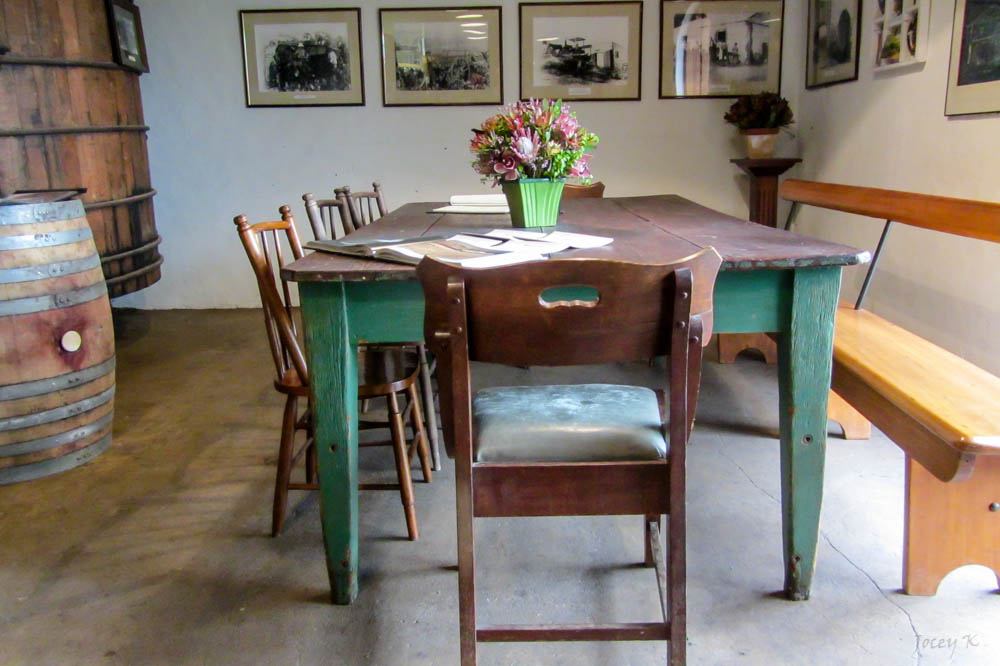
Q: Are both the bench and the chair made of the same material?
A: Yes, both the bench and the chair are made of wood.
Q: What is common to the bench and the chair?
A: The material, both the bench and the chair are wooden.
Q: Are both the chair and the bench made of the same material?
A: Yes, both the chair and the bench are made of wood.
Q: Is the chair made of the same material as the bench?
A: Yes, both the chair and the bench are made of wood.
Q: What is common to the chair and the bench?
A: The material, both the chair and the bench are wooden.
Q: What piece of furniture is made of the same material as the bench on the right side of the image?
A: The chair is made of the same material as the bench.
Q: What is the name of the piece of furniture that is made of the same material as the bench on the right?
A: The piece of furniture is a chair.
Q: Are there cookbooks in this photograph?
A: No, there are no cookbooks.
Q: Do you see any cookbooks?
A: No, there are no cookbooks.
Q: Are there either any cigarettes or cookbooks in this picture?
A: No, there are no cookbooks or cigarettes.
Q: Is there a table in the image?
A: Yes, there is a table.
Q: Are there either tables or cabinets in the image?
A: Yes, there is a table.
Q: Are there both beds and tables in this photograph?
A: No, there is a table but no beds.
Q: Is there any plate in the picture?
A: No, there are no plates.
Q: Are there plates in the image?
A: No, there are no plates.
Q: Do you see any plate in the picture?
A: No, there are no plates.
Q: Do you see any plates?
A: No, there are no plates.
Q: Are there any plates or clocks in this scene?
A: No, there are no plates or clocks.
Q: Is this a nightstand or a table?
A: This is a table.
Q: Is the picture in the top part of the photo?
A: Yes, the picture is in the top of the image.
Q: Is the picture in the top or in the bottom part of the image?
A: The picture is in the top of the image.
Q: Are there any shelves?
A: No, there are no shelves.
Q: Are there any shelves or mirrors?
A: No, there are no shelves or mirrors.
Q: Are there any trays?
A: No, there are no trays.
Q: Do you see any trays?
A: No, there are no trays.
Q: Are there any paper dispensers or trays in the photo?
A: No, there are no trays or paper dispensers.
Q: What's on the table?
A: The flowers are on the table.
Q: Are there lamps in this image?
A: No, there are no lamps.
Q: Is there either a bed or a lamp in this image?
A: No, there are no lamps or beds.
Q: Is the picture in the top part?
A: Yes, the picture is in the top of the image.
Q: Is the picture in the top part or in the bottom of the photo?
A: The picture is in the top of the image.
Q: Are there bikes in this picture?
A: No, there are no bikes.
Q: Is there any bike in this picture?
A: No, there are no bikes.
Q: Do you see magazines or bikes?
A: No, there are no bikes or magazines.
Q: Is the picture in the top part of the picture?
A: Yes, the picture is in the top of the image.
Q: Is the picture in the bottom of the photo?
A: No, the picture is in the top of the image.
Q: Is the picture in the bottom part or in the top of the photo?
A: The picture is in the top of the image.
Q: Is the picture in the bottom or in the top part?
A: The picture is in the top of the image.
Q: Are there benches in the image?
A: Yes, there is a bench.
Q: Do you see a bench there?
A: Yes, there is a bench.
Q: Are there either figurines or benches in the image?
A: Yes, there is a bench.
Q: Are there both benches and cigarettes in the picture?
A: No, there is a bench but no cigarettes.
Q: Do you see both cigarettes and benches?
A: No, there is a bench but no cigarettes.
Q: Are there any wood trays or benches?
A: Yes, there is a wood bench.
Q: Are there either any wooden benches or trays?
A: Yes, there is a wood bench.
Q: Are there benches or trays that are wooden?
A: Yes, the bench is wooden.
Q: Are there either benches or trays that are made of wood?
A: Yes, the bench is made of wood.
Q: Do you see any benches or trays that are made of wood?
A: Yes, the bench is made of wood.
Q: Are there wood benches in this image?
A: Yes, there is a wood bench.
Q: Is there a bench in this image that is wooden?
A: Yes, there is a bench that is wooden.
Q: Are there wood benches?
A: Yes, there is a bench that is made of wood.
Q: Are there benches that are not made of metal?
A: Yes, there is a bench that is made of wood.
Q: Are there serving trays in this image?
A: No, there are no serving trays.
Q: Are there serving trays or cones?
A: No, there are no serving trays or cones.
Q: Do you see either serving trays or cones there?
A: No, there are no serving trays or cones.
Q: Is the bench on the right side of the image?
A: Yes, the bench is on the right of the image.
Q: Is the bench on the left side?
A: No, the bench is on the right of the image.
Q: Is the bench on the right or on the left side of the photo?
A: The bench is on the right of the image.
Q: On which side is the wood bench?
A: The bench is on the right of the image.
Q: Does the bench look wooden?
A: Yes, the bench is wooden.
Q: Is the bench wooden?
A: Yes, the bench is wooden.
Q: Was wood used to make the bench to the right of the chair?
A: Yes, the bench is made of wood.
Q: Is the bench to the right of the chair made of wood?
A: Yes, the bench is made of wood.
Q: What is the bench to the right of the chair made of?
A: The bench is made of wood.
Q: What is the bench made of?
A: The bench is made of wood.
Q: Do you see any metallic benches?
A: No, there is a bench but it is wooden.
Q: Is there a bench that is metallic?
A: No, there is a bench but it is wooden.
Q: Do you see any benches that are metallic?
A: No, there is a bench but it is wooden.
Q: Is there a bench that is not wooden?
A: No, there is a bench but it is wooden.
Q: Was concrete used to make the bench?
A: No, the bench is made of wood.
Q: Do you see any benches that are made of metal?
A: No, there is a bench but it is made of wood.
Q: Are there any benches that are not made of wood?
A: No, there is a bench but it is made of wood.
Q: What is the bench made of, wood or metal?
A: The bench is made of wood.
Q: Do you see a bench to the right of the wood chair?
A: Yes, there is a bench to the right of the chair.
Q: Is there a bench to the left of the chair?
A: No, the bench is to the right of the chair.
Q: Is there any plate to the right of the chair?
A: No, there is a bench to the right of the chair.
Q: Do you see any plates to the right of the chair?
A: No, there is a bench to the right of the chair.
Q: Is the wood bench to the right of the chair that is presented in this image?
A: Yes, the bench is to the right of the chair.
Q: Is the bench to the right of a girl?
A: No, the bench is to the right of the chair.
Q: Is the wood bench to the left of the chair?
A: No, the bench is to the right of the chair.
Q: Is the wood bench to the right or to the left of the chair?
A: The bench is to the right of the chair.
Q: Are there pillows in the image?
A: No, there are no pillows.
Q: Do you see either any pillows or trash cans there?
A: No, there are no pillows or trash cans.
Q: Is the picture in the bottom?
A: No, the picture is in the top of the image.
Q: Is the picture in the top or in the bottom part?
A: The picture is in the top of the image.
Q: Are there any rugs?
A: No, there are no rugs.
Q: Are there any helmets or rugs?
A: No, there are no rugs or helmets.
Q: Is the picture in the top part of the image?
A: Yes, the picture is in the top of the image.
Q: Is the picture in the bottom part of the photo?
A: No, the picture is in the top of the image.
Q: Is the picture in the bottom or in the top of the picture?
A: The picture is in the top of the image.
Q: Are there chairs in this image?
A: Yes, there is a chair.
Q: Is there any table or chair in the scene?
A: Yes, there is a chair.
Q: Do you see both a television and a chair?
A: No, there is a chair but no televisions.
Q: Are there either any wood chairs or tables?
A: Yes, there is a wood chair.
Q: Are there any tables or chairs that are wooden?
A: Yes, the chair is wooden.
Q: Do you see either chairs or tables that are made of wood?
A: Yes, the chair is made of wood.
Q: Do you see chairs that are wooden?
A: Yes, there is a wood chair.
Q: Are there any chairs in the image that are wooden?
A: Yes, there is a chair that is wooden.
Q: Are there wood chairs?
A: Yes, there is a chair that is made of wood.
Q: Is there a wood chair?
A: Yes, there is a chair that is made of wood.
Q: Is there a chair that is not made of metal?
A: Yes, there is a chair that is made of wood.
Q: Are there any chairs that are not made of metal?
A: Yes, there is a chair that is made of wood.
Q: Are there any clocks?
A: No, there are no clocks.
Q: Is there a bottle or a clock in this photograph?
A: No, there are no clocks or bottles.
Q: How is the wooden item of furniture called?
A: The piece of furniture is a chair.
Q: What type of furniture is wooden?
A: The furniture is a chair.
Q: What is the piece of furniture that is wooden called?
A: The piece of furniture is a chair.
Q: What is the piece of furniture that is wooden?
A: The piece of furniture is a chair.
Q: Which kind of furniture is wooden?
A: The furniture is a chair.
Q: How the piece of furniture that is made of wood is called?
A: The piece of furniture is a chair.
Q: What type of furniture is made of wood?
A: The furniture is a chair.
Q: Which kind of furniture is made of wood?
A: The furniture is a chair.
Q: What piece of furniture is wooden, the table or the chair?
A: The chair is wooden.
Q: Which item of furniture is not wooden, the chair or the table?
A: The table is not wooden.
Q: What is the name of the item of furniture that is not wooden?
A: The piece of furniture is a table.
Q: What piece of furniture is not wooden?
A: The piece of furniture is a table.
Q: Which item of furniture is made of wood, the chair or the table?
A: The chair is made of wood.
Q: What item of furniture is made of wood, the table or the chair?
A: The chair is made of wood.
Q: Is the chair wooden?
A: Yes, the chair is wooden.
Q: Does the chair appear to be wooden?
A: Yes, the chair is wooden.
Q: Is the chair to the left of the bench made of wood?
A: Yes, the chair is made of wood.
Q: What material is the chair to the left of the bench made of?
A: The chair is made of wood.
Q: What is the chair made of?
A: The chair is made of wood.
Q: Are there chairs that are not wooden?
A: No, there is a chair but it is wooden.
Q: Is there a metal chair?
A: No, there is a chair but it is made of wood.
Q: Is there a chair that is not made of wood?
A: No, there is a chair but it is made of wood.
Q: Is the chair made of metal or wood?
A: The chair is made of wood.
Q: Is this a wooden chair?
A: Yes, this is a wooden chair.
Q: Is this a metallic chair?
A: No, this is a wooden chair.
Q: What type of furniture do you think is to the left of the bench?
A: The piece of furniture is a chair.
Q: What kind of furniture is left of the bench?
A: The piece of furniture is a chair.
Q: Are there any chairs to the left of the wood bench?
A: Yes, there is a chair to the left of the bench.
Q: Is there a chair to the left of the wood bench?
A: Yes, there is a chair to the left of the bench.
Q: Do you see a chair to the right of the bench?
A: No, the chair is to the left of the bench.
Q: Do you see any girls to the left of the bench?
A: No, there is a chair to the left of the bench.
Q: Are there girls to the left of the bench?
A: No, there is a chair to the left of the bench.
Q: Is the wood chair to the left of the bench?
A: Yes, the chair is to the left of the bench.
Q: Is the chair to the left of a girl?
A: No, the chair is to the left of the bench.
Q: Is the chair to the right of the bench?
A: No, the chair is to the left of the bench.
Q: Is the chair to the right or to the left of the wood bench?
A: The chair is to the left of the bench.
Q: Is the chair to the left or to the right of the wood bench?
A: The chair is to the left of the bench.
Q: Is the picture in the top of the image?
A: Yes, the picture is in the top of the image.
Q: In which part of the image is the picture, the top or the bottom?
A: The picture is in the top of the image.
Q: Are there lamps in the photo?
A: No, there are no lamps.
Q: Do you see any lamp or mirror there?
A: No, there are no lamps or mirrors.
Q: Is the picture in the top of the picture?
A: Yes, the picture is in the top of the image.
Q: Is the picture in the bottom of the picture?
A: No, the picture is in the top of the image.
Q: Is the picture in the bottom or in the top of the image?
A: The picture is in the top of the image.